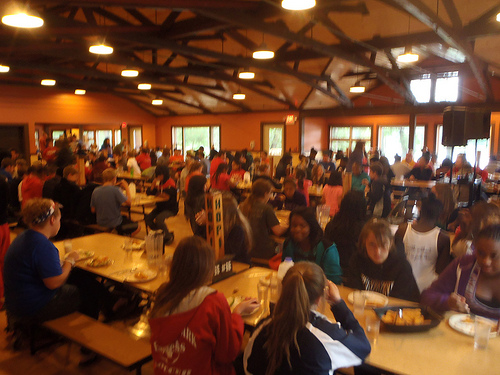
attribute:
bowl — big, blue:
[373, 302, 437, 327]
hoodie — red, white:
[148, 282, 242, 374]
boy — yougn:
[147, 163, 186, 244]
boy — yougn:
[90, 166, 140, 234]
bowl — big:
[372, 304, 444, 334]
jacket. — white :
[144, 283, 243, 372]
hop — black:
[210, 194, 224, 235]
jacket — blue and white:
[234, 295, 372, 374]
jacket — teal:
[280, 237, 343, 286]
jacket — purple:
[416, 252, 498, 317]